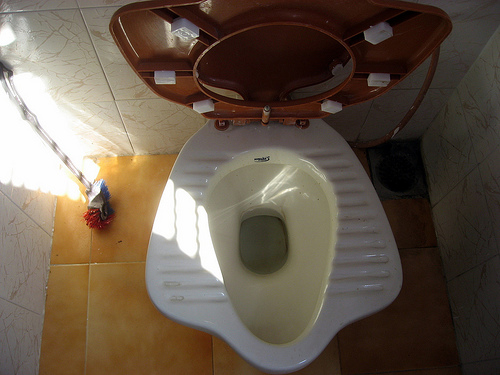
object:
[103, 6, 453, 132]
seat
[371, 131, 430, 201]
cleaner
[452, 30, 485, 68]
wall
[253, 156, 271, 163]
logo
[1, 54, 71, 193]
window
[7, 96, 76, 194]
sunlight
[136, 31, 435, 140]
cushions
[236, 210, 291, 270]
tunnel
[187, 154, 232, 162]
ridge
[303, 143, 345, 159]
ridge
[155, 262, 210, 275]
ridge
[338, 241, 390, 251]
ridge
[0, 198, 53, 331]
tile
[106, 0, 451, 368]
toilet bowl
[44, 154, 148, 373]
floor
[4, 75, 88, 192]
handle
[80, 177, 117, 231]
brush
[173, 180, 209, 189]
line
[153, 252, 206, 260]
line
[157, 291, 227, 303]
line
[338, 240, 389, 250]
line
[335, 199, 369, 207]
line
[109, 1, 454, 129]
lid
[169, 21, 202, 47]
sponge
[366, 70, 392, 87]
sponge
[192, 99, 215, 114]
sponge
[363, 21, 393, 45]
sponge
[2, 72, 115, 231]
scrubber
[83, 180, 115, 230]
bristles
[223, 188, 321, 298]
bowl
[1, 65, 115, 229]
cleaner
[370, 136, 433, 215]
plate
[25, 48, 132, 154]
walls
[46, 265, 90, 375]
tile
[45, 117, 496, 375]
bathroom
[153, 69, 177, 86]
square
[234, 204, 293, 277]
water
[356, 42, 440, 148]
cord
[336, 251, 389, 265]
ridge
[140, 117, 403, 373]
porcelain toilet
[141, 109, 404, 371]
seat